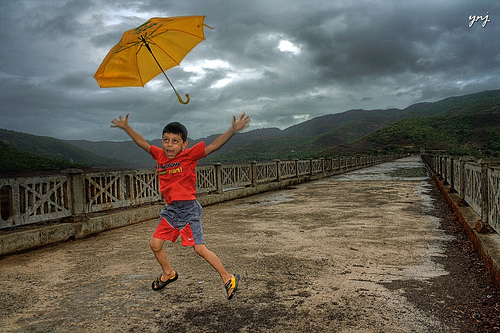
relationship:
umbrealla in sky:
[88, 9, 212, 109] [44, 7, 447, 110]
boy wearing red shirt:
[112, 101, 262, 306] [144, 141, 208, 206]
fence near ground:
[0, 148, 412, 225] [0, 150, 493, 325]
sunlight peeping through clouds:
[182, 57, 242, 91] [0, 0, 500, 143]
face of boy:
[160, 127, 181, 161] [109, 111, 251, 300]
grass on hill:
[12, 124, 44, 159] [322, 116, 500, 156]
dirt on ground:
[384, 243, 498, 327] [0, 150, 493, 325]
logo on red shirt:
[152, 160, 189, 179] [144, 141, 208, 202]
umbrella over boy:
[82, 12, 224, 107] [103, 107, 265, 300]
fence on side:
[0, 148, 412, 225] [16, 212, 152, 246]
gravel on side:
[100, 157, 498, 330] [424, 155, 495, 331]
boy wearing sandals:
[109, 111, 251, 300] [148, 273, 234, 294]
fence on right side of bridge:
[424, 151, 499, 241] [1, 143, 499, 330]